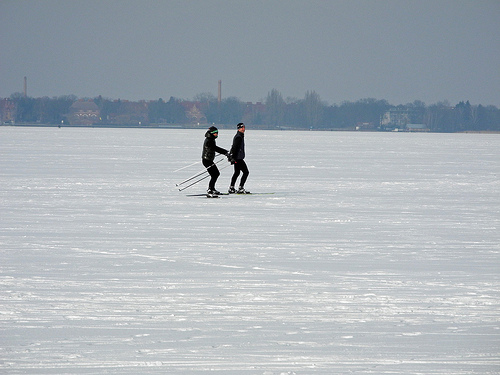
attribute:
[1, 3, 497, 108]
sky — overcast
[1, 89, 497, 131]
trees — hazy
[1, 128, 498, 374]
snow — part, edge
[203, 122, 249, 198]
people — skiing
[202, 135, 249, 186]
clothing — black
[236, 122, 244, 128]
hat — black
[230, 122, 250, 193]
man — holding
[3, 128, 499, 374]
ice — white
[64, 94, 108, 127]
building — part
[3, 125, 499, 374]
floor — part